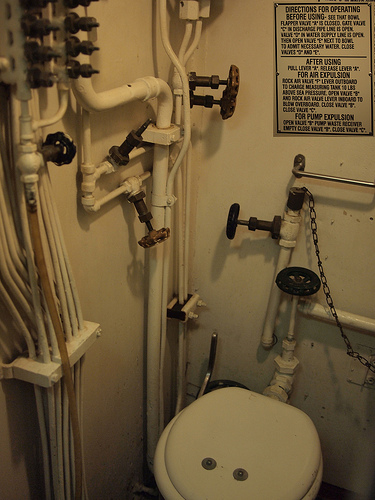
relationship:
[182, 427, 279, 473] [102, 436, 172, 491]
lid on top of toilet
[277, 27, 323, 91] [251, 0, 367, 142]
letters on top of sign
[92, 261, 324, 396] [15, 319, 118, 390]
plumbing inside of bathroom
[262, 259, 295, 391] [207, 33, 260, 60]
pipes on side of wall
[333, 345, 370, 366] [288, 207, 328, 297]
links on top of chain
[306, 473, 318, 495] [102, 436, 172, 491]
seat on top of toilet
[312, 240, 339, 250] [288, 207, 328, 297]
part of chain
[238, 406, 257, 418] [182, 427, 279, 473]
part of lid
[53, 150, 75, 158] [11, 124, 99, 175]
part of bolt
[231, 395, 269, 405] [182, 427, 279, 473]
edge of lid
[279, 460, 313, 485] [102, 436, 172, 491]
part of toilet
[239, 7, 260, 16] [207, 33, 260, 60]
part of wall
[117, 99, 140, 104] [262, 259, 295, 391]
part of pipes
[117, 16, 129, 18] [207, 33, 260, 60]
part of wall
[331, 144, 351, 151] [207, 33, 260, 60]
part of wall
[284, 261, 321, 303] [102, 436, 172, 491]
sink on top of toilet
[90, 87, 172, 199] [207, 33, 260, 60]
piipes attached to wall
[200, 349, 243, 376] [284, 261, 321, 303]
metal beside sink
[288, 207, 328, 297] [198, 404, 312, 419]
chain to flush